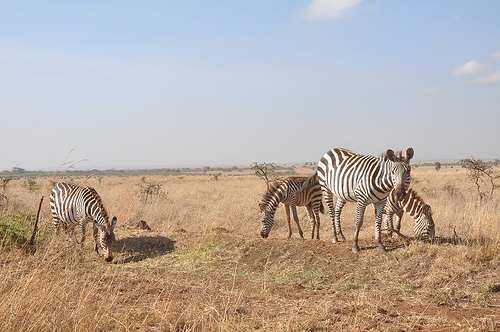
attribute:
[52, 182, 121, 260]
zebra — alone, small, eating, black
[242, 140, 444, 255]
zebras — grouped, larger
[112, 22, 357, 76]
sky — blue, clear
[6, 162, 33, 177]
mountain — rocky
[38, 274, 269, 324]
grass — dry, brown, dried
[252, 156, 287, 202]
tree — small, bare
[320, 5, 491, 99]
clouds — grouped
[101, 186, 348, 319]
field — grassy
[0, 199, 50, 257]
grass — green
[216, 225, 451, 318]
ground — brown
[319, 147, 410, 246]
zebra — largest